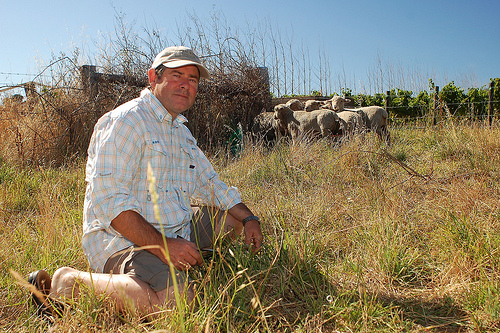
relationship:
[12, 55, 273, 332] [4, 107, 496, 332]
man kneeling in a field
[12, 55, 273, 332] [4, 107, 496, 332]
man kneeling in field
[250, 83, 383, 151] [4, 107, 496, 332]
sheep in field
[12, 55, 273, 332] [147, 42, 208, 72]
man wearing a hat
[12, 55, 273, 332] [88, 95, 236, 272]
man wearing a shirt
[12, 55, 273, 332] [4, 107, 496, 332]
man sitting in field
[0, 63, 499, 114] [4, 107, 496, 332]
fence in field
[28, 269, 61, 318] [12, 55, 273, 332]
shoe of man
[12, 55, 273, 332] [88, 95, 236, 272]
man has a shirt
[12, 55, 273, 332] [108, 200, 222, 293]
man wearing shorts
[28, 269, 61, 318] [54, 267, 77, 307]
shoe on h foot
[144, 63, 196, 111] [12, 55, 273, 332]
head of man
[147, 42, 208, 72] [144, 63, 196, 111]
hat on h head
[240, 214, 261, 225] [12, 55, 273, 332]
wrist watch of man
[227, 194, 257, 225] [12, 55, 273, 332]
arm of man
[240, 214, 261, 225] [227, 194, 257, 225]
wrist watch on arm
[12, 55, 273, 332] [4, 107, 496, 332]
man sitting down in field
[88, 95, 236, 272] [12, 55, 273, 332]
shirt of man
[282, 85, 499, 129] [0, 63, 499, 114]
plants on or side of fence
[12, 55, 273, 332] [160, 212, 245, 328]
man on h knees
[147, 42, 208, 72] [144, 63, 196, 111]
hat on mans head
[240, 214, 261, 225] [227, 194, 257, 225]
wrist watch on h arm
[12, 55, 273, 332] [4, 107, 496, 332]
man sitting on field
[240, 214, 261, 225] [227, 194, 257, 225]
wrist watch on mans arm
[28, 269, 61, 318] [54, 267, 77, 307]
shoe on mans foot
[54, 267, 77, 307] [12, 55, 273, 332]
foot of man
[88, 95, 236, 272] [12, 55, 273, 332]
shirt on man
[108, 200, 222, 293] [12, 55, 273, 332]
shorts on man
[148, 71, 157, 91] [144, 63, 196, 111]
ear on mans head